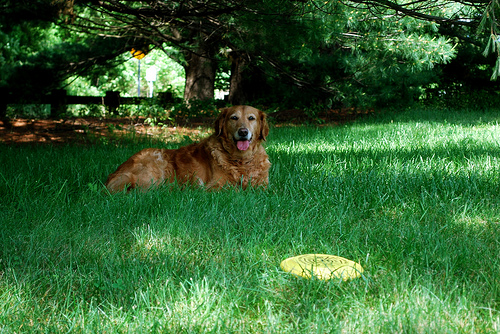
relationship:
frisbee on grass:
[279, 252, 365, 280] [0, 106, 499, 333]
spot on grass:
[265, 122, 500, 150] [0, 106, 499, 333]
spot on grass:
[338, 286, 499, 332] [0, 106, 499, 333]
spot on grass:
[1, 268, 309, 334] [0, 106, 499, 333]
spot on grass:
[132, 224, 178, 251] [0, 106, 499, 333]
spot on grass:
[451, 205, 489, 230] [0, 106, 499, 333]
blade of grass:
[1, 104, 499, 333] [0, 106, 499, 333]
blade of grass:
[477, 303, 499, 316] [0, 106, 499, 333]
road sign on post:
[130, 47, 145, 59] [137, 59, 142, 95]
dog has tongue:
[104, 104, 273, 195] [236, 139, 251, 152]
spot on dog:
[152, 148, 163, 161] [104, 104, 273, 195]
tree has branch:
[0, 0, 493, 110] [378, 1, 499, 28]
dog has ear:
[104, 104, 273, 195] [260, 109, 268, 140]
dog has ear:
[104, 104, 273, 195] [214, 107, 228, 137]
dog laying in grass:
[104, 104, 273, 195] [0, 106, 499, 333]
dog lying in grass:
[104, 104, 273, 195] [0, 106, 499, 333]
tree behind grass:
[0, 0, 493, 110] [0, 106, 499, 333]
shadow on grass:
[346, 105, 499, 128] [0, 106, 499, 333]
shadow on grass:
[267, 145, 499, 161] [0, 106, 499, 333]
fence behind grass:
[1, 83, 229, 116] [0, 106, 499, 333]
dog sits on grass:
[104, 104, 273, 195] [0, 106, 499, 333]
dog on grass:
[104, 104, 273, 195] [0, 106, 499, 333]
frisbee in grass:
[279, 252, 365, 280] [0, 106, 499, 333]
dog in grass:
[104, 104, 273, 195] [0, 106, 499, 333]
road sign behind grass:
[130, 47, 145, 59] [0, 106, 499, 333]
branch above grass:
[378, 1, 499, 28] [0, 106, 499, 333]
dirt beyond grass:
[2, 114, 335, 142] [0, 106, 499, 333]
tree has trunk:
[0, 0, 493, 110] [185, 46, 215, 99]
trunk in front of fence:
[185, 46, 215, 99] [1, 83, 229, 116]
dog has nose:
[104, 104, 273, 195] [237, 128, 249, 135]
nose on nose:
[237, 128, 249, 135] [237, 128, 249, 135]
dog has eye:
[104, 104, 273, 195] [247, 115, 254, 121]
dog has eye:
[104, 104, 273, 195] [228, 114, 239, 121]